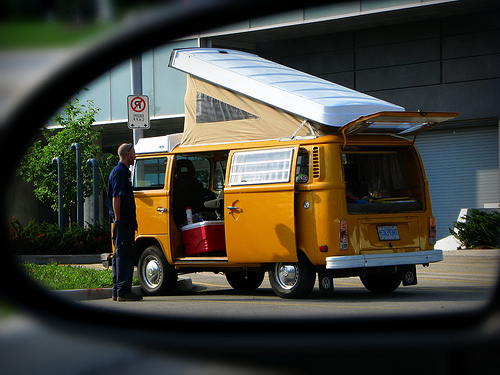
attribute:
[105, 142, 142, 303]
man — blonde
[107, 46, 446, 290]
van — yellow, parked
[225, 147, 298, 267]
door — open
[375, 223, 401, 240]
plate — white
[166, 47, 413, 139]
popup — white, open, angled, raised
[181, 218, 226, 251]
cooler — red, white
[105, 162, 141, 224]
shirt — blue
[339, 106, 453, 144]
window — open